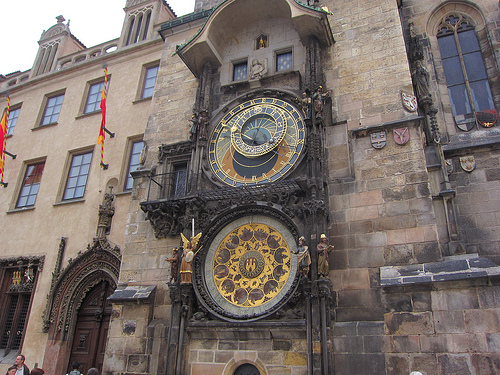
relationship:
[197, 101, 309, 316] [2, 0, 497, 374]
clock on building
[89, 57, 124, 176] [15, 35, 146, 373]
flag on wall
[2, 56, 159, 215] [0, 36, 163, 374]
windows on wall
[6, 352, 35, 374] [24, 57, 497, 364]
man outside building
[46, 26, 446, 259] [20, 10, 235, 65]
building has top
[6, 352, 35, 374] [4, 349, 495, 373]
man on street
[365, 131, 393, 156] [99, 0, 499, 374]
shield on brick wall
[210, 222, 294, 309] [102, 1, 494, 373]
ornate medallion on building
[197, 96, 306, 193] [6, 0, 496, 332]
clock side building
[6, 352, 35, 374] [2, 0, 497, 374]
man near building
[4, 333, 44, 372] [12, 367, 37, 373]
man has jacket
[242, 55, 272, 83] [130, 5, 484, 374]
statue on building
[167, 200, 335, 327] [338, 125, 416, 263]
shield on brick wall